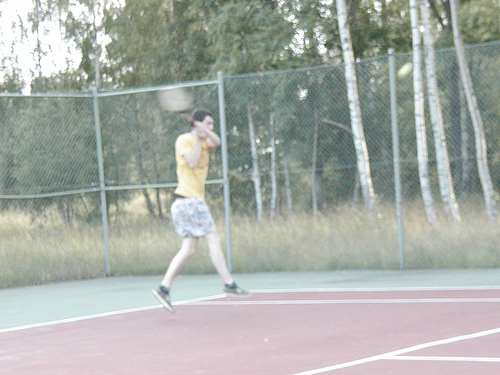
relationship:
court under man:
[1, 265, 498, 372] [151, 104, 251, 313]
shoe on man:
[153, 284, 176, 316] [151, 104, 251, 313]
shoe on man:
[222, 284, 253, 299] [151, 104, 251, 313]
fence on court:
[0, 39, 499, 290] [1, 265, 498, 372]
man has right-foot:
[151, 104, 251, 313] [219, 279, 253, 302]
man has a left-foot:
[151, 104, 251, 313] [153, 284, 176, 316]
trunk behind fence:
[409, 1, 437, 227] [0, 39, 499, 290]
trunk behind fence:
[417, 0, 458, 226] [0, 39, 499, 290]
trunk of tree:
[447, 1, 496, 216] [433, 3, 500, 181]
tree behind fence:
[28, 3, 323, 97] [0, 39, 499, 290]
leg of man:
[163, 199, 198, 288] [151, 104, 251, 313]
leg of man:
[193, 198, 248, 299] [151, 104, 251, 313]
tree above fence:
[433, 3, 500, 181] [0, 39, 499, 290]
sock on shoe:
[159, 282, 169, 293] [153, 284, 176, 316]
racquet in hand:
[158, 82, 195, 125] [193, 122, 211, 134]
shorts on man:
[167, 199, 215, 235] [151, 104, 251, 313]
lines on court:
[291, 327, 499, 374] [1, 265, 498, 372]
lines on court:
[176, 298, 497, 304] [1, 265, 498, 372]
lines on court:
[0, 290, 229, 332] [1, 265, 498, 372]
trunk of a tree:
[334, 1, 377, 214] [201, 0, 395, 217]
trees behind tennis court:
[0, 39, 499, 290] [0, 36, 500, 368]